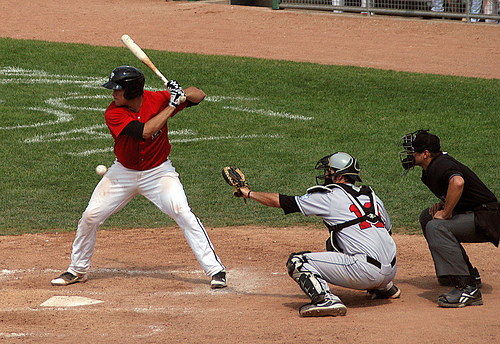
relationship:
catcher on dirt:
[211, 128, 402, 322] [3, 221, 497, 341]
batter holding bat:
[53, 33, 242, 299] [118, 30, 187, 85]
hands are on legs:
[428, 202, 452, 217] [425, 211, 491, 288]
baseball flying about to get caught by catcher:
[55, 153, 160, 208] [218, 148, 404, 320]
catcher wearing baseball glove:
[221, 151, 401, 318] [219, 164, 249, 201]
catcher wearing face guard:
[221, 151, 401, 318] [313, 146, 363, 193]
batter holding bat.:
[50, 65, 228, 289] [102, 12, 193, 87]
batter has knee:
[50, 65, 228, 289] [69, 205, 113, 236]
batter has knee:
[50, 65, 228, 289] [165, 194, 198, 225]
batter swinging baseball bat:
[50, 65, 228, 289] [120, 33, 169, 83]